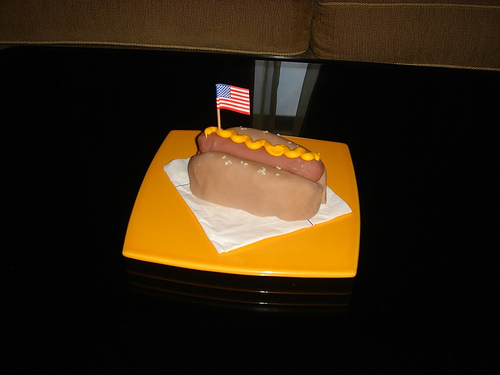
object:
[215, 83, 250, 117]
flag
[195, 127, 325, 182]
hot dog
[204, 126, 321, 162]
mustard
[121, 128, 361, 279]
plate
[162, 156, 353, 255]
napkin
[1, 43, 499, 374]
surface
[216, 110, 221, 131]
toothpick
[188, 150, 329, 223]
hot dog bun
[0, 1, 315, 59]
cushion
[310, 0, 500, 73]
cushion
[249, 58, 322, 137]
window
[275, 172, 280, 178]
sesame seed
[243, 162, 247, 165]
sesame seed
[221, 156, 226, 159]
sesame seed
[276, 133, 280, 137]
sesame seed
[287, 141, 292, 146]
sesame seed